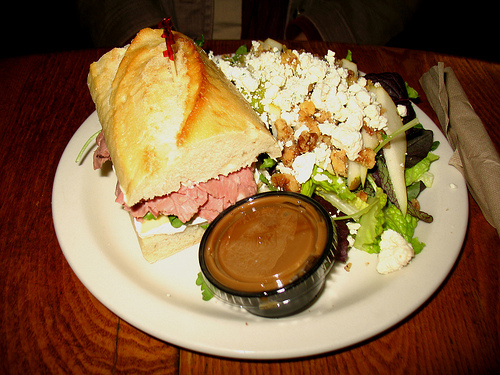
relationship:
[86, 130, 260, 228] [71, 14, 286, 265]
meat in sandwich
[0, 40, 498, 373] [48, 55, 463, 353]
brown table under plate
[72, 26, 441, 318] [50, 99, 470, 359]
food on plate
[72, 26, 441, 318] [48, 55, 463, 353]
food on plate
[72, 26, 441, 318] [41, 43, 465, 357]
food on dish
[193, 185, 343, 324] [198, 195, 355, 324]
gravy on container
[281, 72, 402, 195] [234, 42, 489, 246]
cheese around salad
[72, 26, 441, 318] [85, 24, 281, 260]
food next to sandwich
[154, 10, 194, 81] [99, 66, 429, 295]
toothpick in food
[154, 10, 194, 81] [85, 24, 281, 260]
toothpick in sandwich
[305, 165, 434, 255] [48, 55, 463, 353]
green food on plate